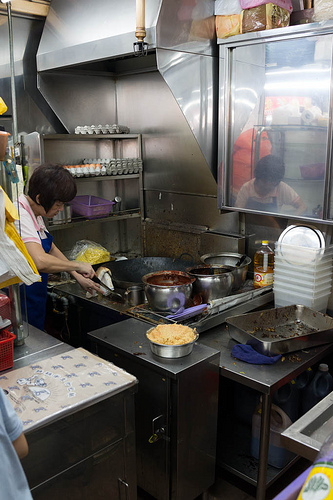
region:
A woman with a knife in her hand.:
[88, 277, 119, 306]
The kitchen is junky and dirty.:
[77, 202, 302, 372]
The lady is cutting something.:
[63, 254, 130, 309]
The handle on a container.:
[145, 420, 174, 449]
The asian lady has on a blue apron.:
[23, 229, 56, 319]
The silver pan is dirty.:
[236, 310, 315, 355]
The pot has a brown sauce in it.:
[142, 265, 199, 299]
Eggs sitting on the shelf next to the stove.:
[67, 153, 147, 177]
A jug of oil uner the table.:
[246, 403, 314, 461]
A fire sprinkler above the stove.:
[132, 6, 154, 66]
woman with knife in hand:
[17, 161, 127, 312]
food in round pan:
[140, 313, 202, 361]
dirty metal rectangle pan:
[223, 303, 324, 364]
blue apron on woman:
[25, 226, 62, 325]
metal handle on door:
[139, 408, 167, 446]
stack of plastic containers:
[277, 243, 327, 314]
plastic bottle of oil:
[250, 239, 276, 289]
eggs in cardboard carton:
[66, 159, 105, 179]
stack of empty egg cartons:
[102, 151, 143, 175]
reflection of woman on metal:
[227, 148, 305, 222]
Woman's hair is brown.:
[18, 161, 78, 222]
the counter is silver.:
[82, 310, 223, 380]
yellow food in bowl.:
[141, 319, 196, 357]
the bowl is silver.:
[141, 318, 197, 356]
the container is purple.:
[67, 189, 119, 221]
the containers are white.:
[267, 231, 330, 312]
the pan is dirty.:
[219, 299, 326, 351]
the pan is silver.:
[218, 298, 328, 354]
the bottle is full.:
[244, 234, 272, 292]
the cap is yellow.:
[256, 235, 271, 246]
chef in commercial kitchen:
[27, 16, 328, 470]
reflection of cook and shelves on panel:
[201, 19, 324, 220]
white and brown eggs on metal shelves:
[26, 103, 143, 180]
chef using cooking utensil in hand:
[14, 157, 139, 312]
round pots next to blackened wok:
[93, 232, 247, 324]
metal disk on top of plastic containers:
[264, 215, 322, 314]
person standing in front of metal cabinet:
[0, 380, 47, 491]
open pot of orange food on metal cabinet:
[106, 308, 218, 458]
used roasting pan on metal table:
[206, 287, 319, 475]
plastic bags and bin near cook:
[2, 158, 44, 370]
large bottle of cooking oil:
[252, 239, 273, 289]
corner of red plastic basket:
[1, 329, 15, 370]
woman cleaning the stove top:
[6, 161, 103, 330]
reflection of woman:
[232, 153, 305, 215]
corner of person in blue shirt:
[0, 388, 33, 497]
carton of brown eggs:
[60, 162, 106, 175]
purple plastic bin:
[74, 193, 113, 217]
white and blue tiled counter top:
[0, 346, 137, 432]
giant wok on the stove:
[87, 251, 197, 289]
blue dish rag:
[229, 342, 281, 363]